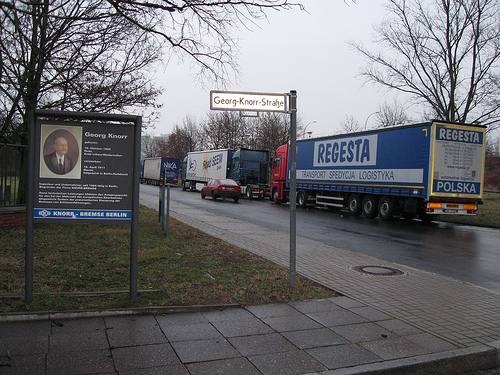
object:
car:
[201, 177, 242, 202]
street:
[140, 184, 499, 290]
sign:
[211, 90, 297, 286]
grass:
[0, 202, 342, 314]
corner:
[294, 233, 499, 372]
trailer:
[269, 119, 488, 223]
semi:
[270, 118, 433, 221]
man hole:
[352, 265, 405, 276]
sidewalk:
[140, 193, 500, 374]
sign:
[38, 209, 129, 217]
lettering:
[214, 96, 284, 108]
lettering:
[317, 138, 370, 163]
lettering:
[439, 128, 479, 143]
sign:
[26, 108, 143, 223]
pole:
[130, 221, 139, 300]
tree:
[1, 0, 308, 146]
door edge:
[431, 121, 485, 200]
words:
[37, 191, 129, 205]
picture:
[39, 124, 81, 179]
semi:
[140, 156, 180, 187]